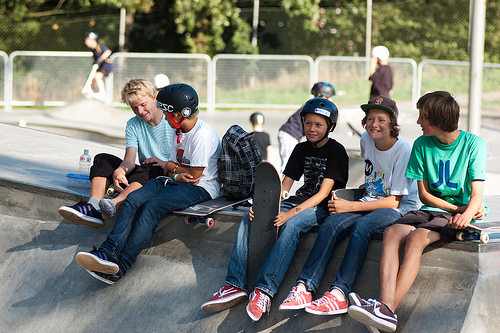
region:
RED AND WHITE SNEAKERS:
[195, 272, 276, 327]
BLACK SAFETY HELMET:
[295, 92, 340, 154]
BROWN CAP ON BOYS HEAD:
[354, 92, 404, 145]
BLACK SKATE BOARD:
[237, 152, 291, 317]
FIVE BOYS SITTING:
[52, 72, 496, 331]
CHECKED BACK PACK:
[211, 114, 261, 209]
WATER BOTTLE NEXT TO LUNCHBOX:
[62, 134, 101, 201]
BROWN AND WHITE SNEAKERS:
[343, 284, 408, 331]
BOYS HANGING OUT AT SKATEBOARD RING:
[0, 37, 499, 332]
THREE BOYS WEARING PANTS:
[81, 159, 421, 331]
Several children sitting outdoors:
[57, 77, 486, 324]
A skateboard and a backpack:
[176, 126, 256, 234]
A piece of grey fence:
[186, 51, 303, 111]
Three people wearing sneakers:
[201, 266, 411, 327]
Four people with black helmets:
[157, 81, 343, 144]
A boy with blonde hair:
[105, 75, 157, 127]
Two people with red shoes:
[188, 268, 348, 323]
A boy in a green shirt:
[414, 91, 484, 213]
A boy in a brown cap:
[352, 93, 414, 206]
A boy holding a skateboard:
[233, 99, 348, 224]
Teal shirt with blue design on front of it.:
[418, 139, 478, 191]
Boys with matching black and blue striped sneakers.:
[68, 69, 225, 271]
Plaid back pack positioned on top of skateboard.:
[220, 119, 263, 198]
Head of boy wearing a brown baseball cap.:
[358, 93, 403, 150]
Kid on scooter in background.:
[67, 24, 119, 103]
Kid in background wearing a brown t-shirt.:
[358, 24, 403, 98]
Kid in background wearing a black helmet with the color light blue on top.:
[278, 77, 335, 154]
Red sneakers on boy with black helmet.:
[201, 272, 274, 326]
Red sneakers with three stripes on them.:
[289, 274, 347, 326]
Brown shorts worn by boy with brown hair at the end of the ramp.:
[392, 198, 486, 253]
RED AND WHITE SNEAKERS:
[197, 281, 346, 327]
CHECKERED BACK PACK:
[211, 120, 268, 207]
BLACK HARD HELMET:
[301, 83, 343, 129]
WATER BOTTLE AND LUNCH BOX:
[60, 139, 98, 199]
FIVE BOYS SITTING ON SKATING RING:
[9, 81, 490, 331]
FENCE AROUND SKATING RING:
[29, 44, 499, 104]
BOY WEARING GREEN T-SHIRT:
[388, 96, 498, 241]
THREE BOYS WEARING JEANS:
[89, 141, 420, 304]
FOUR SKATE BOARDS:
[155, 150, 498, 257]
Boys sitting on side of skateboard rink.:
[43, 73, 485, 327]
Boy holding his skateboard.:
[201, 96, 348, 322]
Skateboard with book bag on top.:
[175, 119, 253, 224]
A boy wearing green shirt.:
[401, 133, 484, 223]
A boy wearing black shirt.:
[276, 141, 351, 199]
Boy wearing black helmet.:
[156, 81, 198, 130]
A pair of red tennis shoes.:
[197, 277, 276, 329]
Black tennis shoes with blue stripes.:
[75, 247, 124, 289]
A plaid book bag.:
[218, 121, 258, 201]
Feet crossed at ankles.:
[346, 289, 411, 331]